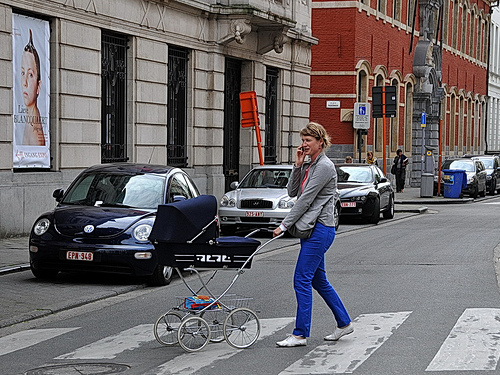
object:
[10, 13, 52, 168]
advertisment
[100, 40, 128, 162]
window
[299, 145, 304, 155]
phone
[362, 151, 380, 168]
people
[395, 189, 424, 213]
sidewalk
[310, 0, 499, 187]
building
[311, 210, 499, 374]
road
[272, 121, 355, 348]
woman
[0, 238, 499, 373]
street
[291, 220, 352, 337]
pants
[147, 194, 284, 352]
stroller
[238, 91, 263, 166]
sign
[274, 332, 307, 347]
shoe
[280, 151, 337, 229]
sweater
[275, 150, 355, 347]
lady wearing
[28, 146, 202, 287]
car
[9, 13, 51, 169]
white sign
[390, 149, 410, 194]
person wearing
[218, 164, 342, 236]
silver car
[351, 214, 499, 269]
street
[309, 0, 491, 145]
red building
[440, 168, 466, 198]
trash can